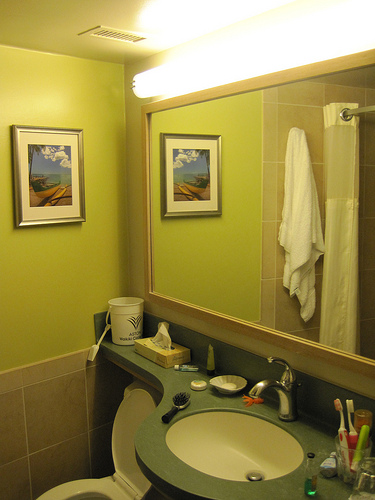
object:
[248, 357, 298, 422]
faucet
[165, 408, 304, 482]
sink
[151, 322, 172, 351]
tissues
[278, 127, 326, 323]
towel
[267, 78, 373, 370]
shower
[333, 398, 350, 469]
toothbrushes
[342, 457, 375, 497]
drinking glass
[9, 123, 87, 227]
frame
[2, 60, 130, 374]
wall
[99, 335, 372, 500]
counter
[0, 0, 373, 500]
hotel bathroom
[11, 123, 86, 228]
picture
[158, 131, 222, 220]
picture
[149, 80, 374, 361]
wall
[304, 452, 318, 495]
mouthwash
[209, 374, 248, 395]
dish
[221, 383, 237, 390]
soap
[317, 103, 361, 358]
shower curtain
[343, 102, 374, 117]
rod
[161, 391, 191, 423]
brush